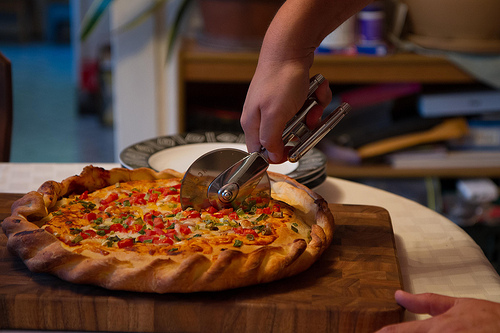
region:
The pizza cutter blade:
[171, 137, 278, 217]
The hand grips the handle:
[244, 54, 353, 174]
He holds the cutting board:
[375, 279, 491, 331]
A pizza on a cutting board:
[1, 166, 344, 330]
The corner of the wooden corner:
[347, 195, 398, 259]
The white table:
[407, 190, 498, 293]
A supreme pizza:
[17, 168, 334, 282]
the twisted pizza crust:
[62, 251, 314, 288]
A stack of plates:
[288, 157, 330, 189]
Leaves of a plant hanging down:
[75, 1, 185, 64]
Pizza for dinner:
[17, 157, 341, 288]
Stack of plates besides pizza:
[114, 118, 323, 188]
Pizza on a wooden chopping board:
[17, 185, 353, 330]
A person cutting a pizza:
[20, 72, 442, 274]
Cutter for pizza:
[135, 83, 373, 240]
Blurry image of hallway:
[5, 26, 115, 166]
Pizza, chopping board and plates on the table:
[3, 146, 383, 303]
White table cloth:
[404, 225, 499, 272]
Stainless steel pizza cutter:
[167, 70, 450, 262]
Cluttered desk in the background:
[170, 36, 476, 179]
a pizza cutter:
[180, 148, 273, 215]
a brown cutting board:
[248, 294, 330, 330]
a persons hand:
[390, 306, 483, 331]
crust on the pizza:
[112, 260, 210, 290]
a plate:
[136, 139, 212, 161]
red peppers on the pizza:
[126, 206, 161, 232]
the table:
[407, 237, 481, 299]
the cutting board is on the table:
[336, 218, 398, 296]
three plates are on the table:
[299, 160, 341, 190]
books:
[391, 105, 475, 160]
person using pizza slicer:
[168, 62, 378, 221]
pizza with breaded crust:
[10, 154, 366, 299]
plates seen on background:
[123, 118, 360, 203]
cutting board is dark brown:
[0, 193, 414, 331]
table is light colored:
[348, 174, 499, 319]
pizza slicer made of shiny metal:
[169, 68, 361, 218]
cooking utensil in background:
[355, 114, 472, 165]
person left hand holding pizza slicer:
[236, 1, 411, 177]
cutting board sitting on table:
[326, 174, 478, 329]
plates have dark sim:
[104, 118, 342, 195]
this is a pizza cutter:
[174, 69, 354, 207]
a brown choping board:
[3, 190, 414, 332]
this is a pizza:
[2, 162, 333, 288]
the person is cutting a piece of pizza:
[165, 0, 350, 209]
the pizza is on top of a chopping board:
[1, 163, 412, 331]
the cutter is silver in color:
[172, 72, 351, 212]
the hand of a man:
[220, 0, 370, 158]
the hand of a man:
[375, 285, 499, 327]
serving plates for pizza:
[109, 125, 332, 191]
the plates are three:
[120, 127, 330, 189]